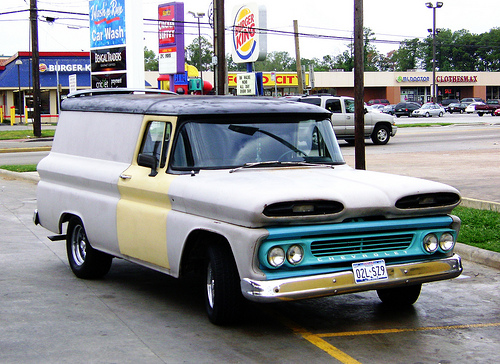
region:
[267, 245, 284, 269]
headlight on a car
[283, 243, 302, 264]
headlight on a car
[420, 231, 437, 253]
headlight on a car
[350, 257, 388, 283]
licesnse plate on a car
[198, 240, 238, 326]
front wheel of a car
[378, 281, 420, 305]
front wheel of a car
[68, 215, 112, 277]
back wheel of a car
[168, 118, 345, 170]
windshield of a car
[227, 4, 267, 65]
a sign for burger king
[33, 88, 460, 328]
An old Chevrolet truck.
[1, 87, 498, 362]
An old truck parked in a parking lot.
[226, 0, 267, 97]
A large Burger King sign.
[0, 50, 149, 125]
A Burger King franchise across the street.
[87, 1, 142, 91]
A large sign with multiple business names on it.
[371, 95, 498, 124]
Cars parked in a parking lot.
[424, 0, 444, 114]
A large pole with two lights attached.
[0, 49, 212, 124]
Playground equipment is next to the Burger King.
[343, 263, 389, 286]
part of a plate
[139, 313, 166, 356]
part of a floor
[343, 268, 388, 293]
part of a plate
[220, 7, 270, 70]
a sign for a burger king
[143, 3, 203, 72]
a sign for a buffet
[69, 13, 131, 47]
a sign for a car wash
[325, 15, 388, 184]
a pole for a power line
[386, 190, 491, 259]
a patch of green grass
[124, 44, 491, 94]
a row of trees in the background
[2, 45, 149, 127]
a Burger King building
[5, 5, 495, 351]
old Chevy with no back windows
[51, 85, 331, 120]
top of Chevy with rack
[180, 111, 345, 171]
a Chevrolet car's windshield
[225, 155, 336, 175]
Chevy's windshield wiper blade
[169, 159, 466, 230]
a Chevrolet car's hood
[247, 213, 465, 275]
a Chevrolet car's grill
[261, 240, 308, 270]
a pair of headlights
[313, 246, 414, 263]
word Chevrolet painted on car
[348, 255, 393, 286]
the Chevy's license plate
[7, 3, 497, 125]
strip mall with marquee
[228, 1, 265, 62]
a Burger King restaurant sign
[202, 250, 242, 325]
black rubber tire with metal rim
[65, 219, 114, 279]
black rubber tire with metal rim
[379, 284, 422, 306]
black rubber tire with metal rim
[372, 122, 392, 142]
black rubber tire with metal rim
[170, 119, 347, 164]
a truck's windshield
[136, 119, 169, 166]
a truck's passenger window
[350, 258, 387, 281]
a license plate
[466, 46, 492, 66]
green leaves on the tree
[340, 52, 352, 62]
green leaves on the tree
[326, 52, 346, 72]
green leaves on the tree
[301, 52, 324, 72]
green leaves on the tree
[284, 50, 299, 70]
green leaves on the tree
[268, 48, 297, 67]
green leaves on the tree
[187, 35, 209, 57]
green leaves on the tree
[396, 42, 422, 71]
green leaves on the tree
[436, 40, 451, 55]
green leaves on the tree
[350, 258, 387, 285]
White and blue license plate on a truck.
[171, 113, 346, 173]
A front windshield on a truck.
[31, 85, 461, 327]
A grey truck with yellow door and front blue grill.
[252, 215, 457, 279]
Blue front section of truck with headlights on each side.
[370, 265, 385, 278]
SZ9 on a truck license plate.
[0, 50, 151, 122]
A blue, red and white Burger King.